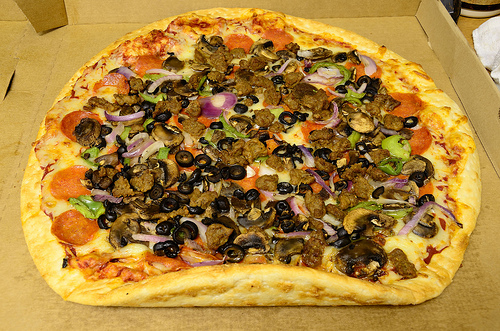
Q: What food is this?
A: Pizza.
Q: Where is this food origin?
A: Italy.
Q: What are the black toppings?
A: Olives.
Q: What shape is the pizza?
A: Round.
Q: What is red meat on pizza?
A: Pepperoni.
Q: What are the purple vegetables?
A: Onion.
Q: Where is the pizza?
A: Box.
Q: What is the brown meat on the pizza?
A: Sausage.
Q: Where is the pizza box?
A: On table.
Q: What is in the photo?
A: Food.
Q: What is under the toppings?
A: Cheese.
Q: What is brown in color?
A: The box.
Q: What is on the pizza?
A: Olives.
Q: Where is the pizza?
A: In a box.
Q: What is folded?
A: The pizza.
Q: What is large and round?
A: The pizza.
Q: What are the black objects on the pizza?
A: Olive slices.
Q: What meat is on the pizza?
A: Pepperoni.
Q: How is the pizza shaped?
A: Round.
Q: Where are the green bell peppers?
A: On the pizza.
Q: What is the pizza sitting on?
A: Cardboard box.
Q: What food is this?
A: Pizza.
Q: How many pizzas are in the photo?
A: One.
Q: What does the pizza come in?
A: Box.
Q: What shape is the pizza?
A: Round.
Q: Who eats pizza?
A: People.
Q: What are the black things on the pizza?
A: Olives.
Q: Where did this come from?
A: Restaurant.